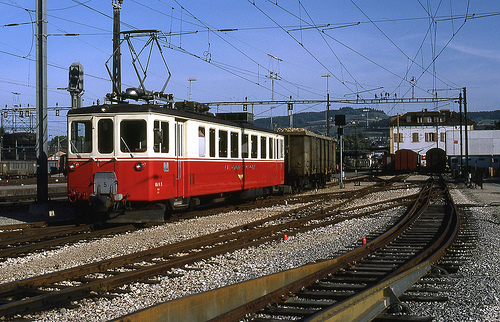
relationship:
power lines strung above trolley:
[0, 0, 500, 110] [65, 98, 297, 199]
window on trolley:
[198, 125, 205, 156] [65, 101, 285, 213]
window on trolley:
[208, 126, 214, 157] [65, 101, 285, 213]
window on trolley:
[218, 127, 229, 157] [65, 101, 285, 213]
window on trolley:
[229, 129, 239, 158] [65, 101, 285, 213]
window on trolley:
[242, 132, 249, 158] [65, 101, 285, 213]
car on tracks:
[65, 103, 338, 228] [1, 168, 461, 320]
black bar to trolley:
[109, 26, 171, 93] [64, 106, 289, 222]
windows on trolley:
[66, 116, 146, 157] [64, 106, 289, 222]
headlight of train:
[127, 159, 149, 176] [62, 92, 343, 222]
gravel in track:
[0, 179, 499, 318] [202, 172, 478, 319]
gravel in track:
[15, 172, 424, 317] [0, 179, 419, 319]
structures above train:
[7, 7, 469, 105] [48, 84, 386, 225]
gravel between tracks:
[0, 179, 499, 318] [113, 172, 455, 319]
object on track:
[354, 224, 375, 249] [118, 174, 469, 315]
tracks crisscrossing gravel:
[403, 208, 459, 293] [223, 252, 271, 277]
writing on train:
[216, 160, 252, 170] [61, 91, 343, 205]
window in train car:
[70, 120, 91, 152] [65, 103, 283, 213]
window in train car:
[93, 115, 114, 152] [65, 103, 283, 213]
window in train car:
[120, 116, 146, 151] [65, 103, 283, 213]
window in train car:
[153, 119, 167, 151] [65, 103, 283, 213]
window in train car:
[209, 127, 214, 157] [65, 103, 283, 213]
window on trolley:
[120, 119, 147, 153] [60, 68, 370, 198]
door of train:
[96, 117, 118, 195] [67, 107, 336, 202]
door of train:
[173, 116, 185, 196] [67, 107, 336, 202]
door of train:
[173, 116, 185, 196] [55, 101, 345, 193]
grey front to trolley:
[90, 169, 120, 196] [63, 28, 285, 226]